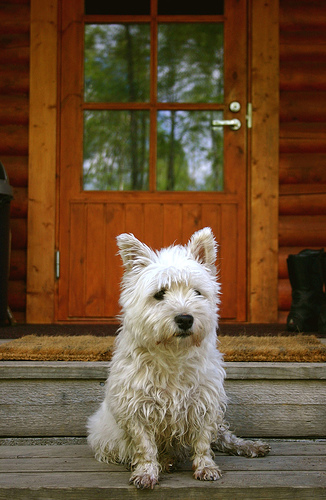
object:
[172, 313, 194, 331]
nose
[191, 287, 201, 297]
eye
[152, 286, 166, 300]
eye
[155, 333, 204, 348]
fur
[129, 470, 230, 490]
claws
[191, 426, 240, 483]
leg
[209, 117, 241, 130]
handle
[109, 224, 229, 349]
face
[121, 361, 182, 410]
fur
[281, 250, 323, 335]
boots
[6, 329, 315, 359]
mat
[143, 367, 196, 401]
fur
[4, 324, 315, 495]
porch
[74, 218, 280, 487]
dog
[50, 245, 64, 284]
hinge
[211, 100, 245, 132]
lock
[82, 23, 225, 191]
panes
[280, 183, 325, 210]
plank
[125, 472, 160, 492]
paw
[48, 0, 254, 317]
door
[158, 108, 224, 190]
window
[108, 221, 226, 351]
head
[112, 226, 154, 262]
ear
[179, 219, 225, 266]
ear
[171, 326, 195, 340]
mouth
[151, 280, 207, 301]
eyes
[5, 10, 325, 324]
building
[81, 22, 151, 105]
window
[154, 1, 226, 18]
window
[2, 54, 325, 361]
building